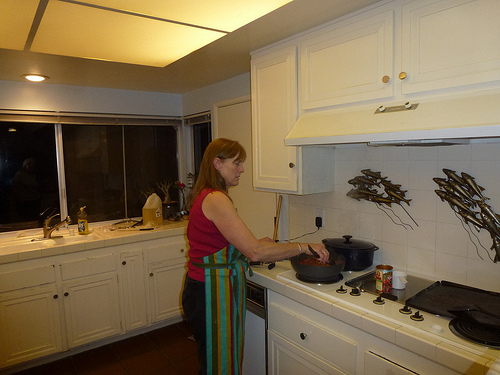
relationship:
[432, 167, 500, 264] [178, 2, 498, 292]
fish sculpture on wall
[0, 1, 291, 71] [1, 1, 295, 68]
light fixture in ceiling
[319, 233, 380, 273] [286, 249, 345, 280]
pot behind skillet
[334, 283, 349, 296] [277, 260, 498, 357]
knob for stove top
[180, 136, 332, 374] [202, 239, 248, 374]
woman wearing apron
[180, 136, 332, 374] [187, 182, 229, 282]
woman wearing shirt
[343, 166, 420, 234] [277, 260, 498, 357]
fish sculpture above stove top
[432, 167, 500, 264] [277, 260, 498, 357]
fish sculpture above stove top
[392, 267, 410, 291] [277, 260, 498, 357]
mearuring cup on stove top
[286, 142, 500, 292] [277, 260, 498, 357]
tile above stove top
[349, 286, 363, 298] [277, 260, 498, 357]
knob on stove top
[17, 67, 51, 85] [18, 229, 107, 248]
light fixture above kitchen sink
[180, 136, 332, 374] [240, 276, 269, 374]
woman near dishwasher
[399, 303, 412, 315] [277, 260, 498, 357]
knob on stove top